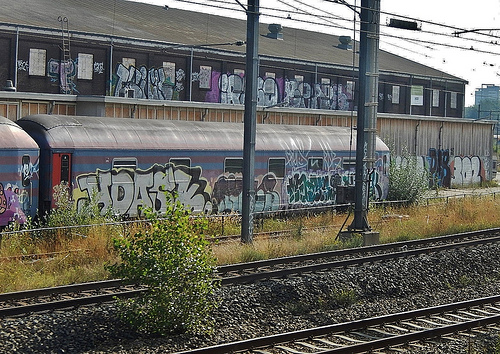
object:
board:
[467, 305, 498, 317]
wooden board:
[383, 320, 419, 333]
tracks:
[178, 290, 500, 353]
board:
[53, 150, 75, 207]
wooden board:
[292, 340, 321, 351]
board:
[368, 325, 402, 337]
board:
[367, 327, 397, 338]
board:
[443, 310, 469, 321]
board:
[402, 318, 432, 331]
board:
[334, 334, 364, 344]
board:
[414, 318, 445, 327]